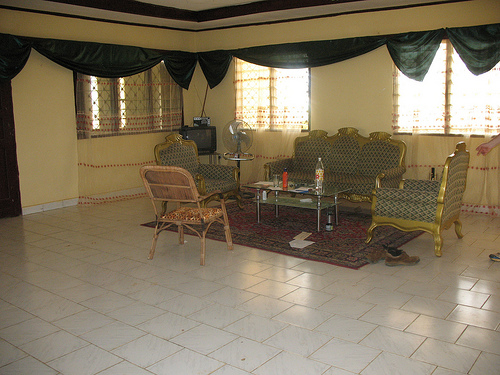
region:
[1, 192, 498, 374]
Dirty white tiled floor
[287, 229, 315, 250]
Two white pieces of paper on the ground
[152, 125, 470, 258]
Gold sofa and chair set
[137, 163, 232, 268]
Light brown wicker chair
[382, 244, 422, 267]
Dirty leather brown boot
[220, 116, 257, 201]
Silver metal standing fan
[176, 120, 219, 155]
Bulky old black television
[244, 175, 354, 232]
Glass top table with metal legs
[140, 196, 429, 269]
Red oriental floor rug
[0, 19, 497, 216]
Black valance hanging around a room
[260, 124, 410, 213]
patterned sofa against wall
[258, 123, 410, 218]
gold trimmed sofa near wall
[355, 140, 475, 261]
patterned chair on right of sofa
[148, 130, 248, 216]
patterned chair on left of sofa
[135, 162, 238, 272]
wicker chair with patterned cushion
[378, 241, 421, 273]
brown shoe on tile floor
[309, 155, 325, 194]
plastic bottle on table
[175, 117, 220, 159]
black television in far corner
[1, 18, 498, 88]
dark green curtain valance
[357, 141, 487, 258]
ornate gold chair next to a table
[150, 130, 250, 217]
ornate gold chair next to a table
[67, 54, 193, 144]
window covered by a sheer curtain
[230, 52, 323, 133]
window covered by a sheer curtain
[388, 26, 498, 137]
window covered by a sheer curtain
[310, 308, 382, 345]
white tile in the floor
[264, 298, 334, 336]
white tile in the floor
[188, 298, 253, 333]
white tile in the floor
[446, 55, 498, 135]
part of a window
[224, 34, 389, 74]
a long green curtain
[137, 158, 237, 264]
a brown chair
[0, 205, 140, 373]
part of a white floor tile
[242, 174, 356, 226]
a small glass table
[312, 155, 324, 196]
a tall plastic bottle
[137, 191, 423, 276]
a large area rug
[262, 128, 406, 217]
a small sofa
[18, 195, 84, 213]
a section of white wall trim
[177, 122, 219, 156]
a small black t.v.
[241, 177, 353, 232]
the coffee table made of glass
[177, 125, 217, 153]
the tv in the corner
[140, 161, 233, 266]
the empty chair on the tiled floor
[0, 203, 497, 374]
the floor covered in tiles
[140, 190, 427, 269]
the area rug on the tiled floor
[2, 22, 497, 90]
the curtains hanging on the wall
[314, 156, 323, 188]
the bottle on the coffee table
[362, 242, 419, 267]
the shoes on the floor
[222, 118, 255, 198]
the standing fan next to the tv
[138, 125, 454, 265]
the empty chairs in the room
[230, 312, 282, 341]
Tile on the floor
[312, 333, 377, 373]
Tile on the floor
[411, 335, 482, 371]
Tile on the floor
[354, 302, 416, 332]
Tile on the floor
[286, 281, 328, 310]
Tile on the floor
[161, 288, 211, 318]
Tile on the floor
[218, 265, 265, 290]
Tile on the floor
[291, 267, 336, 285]
Tile on the floor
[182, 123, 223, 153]
tv sitting on a stand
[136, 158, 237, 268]
brown chair with cushion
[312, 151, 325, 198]
plastic bottle on the stand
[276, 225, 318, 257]
white papers on the rug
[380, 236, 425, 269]
shoe on the tiled floor